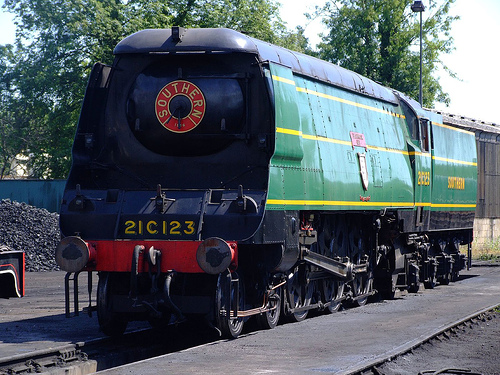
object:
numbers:
[162, 220, 167, 235]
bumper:
[56, 235, 239, 274]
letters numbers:
[184, 221, 196, 235]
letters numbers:
[418, 171, 422, 185]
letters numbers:
[447, 177, 451, 190]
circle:
[153, 80, 205, 134]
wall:
[471, 131, 500, 270]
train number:
[169, 221, 180, 235]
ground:
[0, 246, 500, 374]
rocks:
[3, 195, 58, 267]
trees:
[6, 0, 290, 184]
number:
[138, 220, 143, 234]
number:
[124, 221, 136, 235]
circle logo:
[154, 80, 206, 133]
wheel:
[216, 293, 246, 341]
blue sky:
[0, 0, 51, 51]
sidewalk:
[162, 271, 500, 375]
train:
[52, 27, 479, 339]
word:
[454, 177, 456, 190]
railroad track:
[1, 323, 226, 373]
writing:
[417, 171, 430, 186]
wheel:
[258, 276, 281, 328]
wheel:
[286, 272, 315, 322]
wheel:
[322, 277, 344, 314]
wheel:
[354, 267, 370, 308]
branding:
[447, 176, 464, 190]